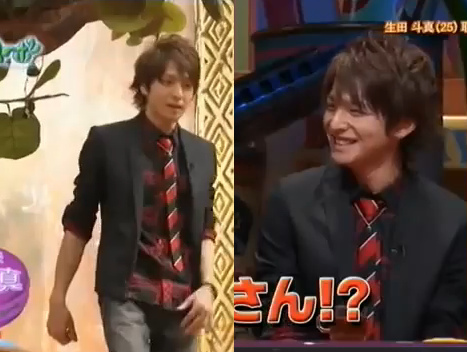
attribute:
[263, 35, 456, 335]
man — smiling, young, sitting, light skinned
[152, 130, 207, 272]
tie — striped, red, black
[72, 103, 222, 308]
coat — navy blue, black, folded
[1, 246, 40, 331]
symbols — purple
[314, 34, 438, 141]
hair — black, long, disordered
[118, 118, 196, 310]
shirt — red, black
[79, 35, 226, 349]
man — walking, slim, light skinned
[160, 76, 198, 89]
eyes — slim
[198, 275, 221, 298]
bracelet — black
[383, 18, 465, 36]
characters — orange